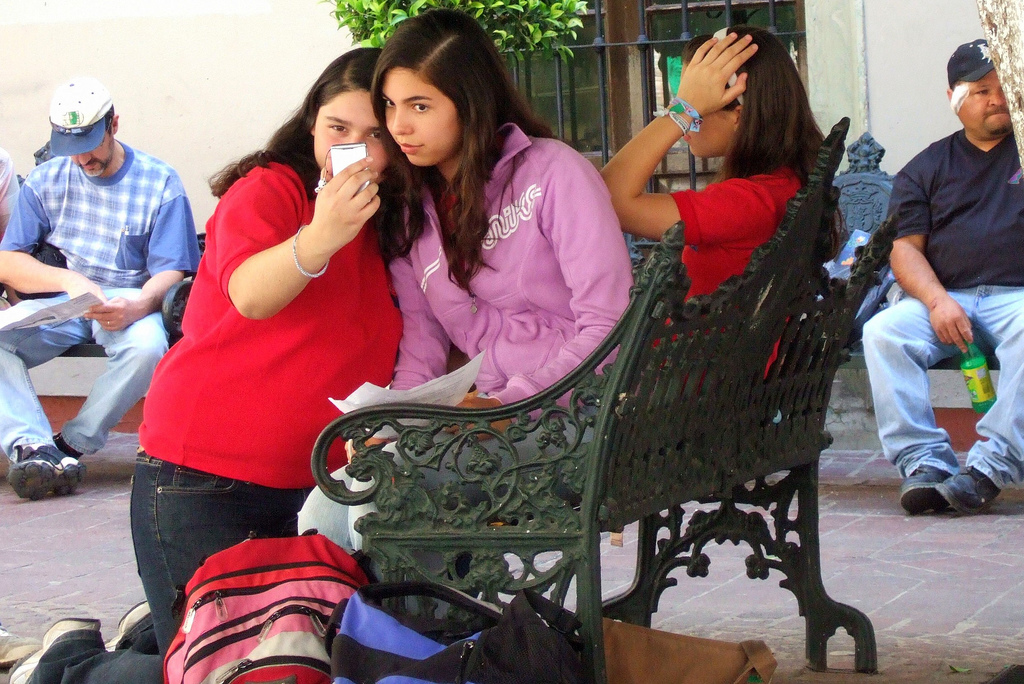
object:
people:
[578, 12, 866, 679]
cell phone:
[308, 130, 388, 196]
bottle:
[945, 312, 1001, 433]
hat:
[39, 61, 122, 163]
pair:
[0, 294, 177, 459]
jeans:
[0, 283, 173, 458]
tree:
[310, 0, 621, 161]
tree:
[332, 0, 617, 143]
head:
[357, 0, 554, 176]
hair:
[361, 4, 569, 308]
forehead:
[370, 72, 450, 99]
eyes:
[402, 89, 443, 119]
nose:
[381, 113, 422, 142]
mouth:
[381, 130, 438, 157]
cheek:
[417, 94, 466, 158]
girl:
[289, 0, 630, 573]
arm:
[181, 186, 341, 327]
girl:
[9, 47, 404, 679]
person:
[0, 80, 214, 510]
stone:
[874, 574, 1006, 639]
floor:
[0, 420, 1017, 678]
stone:
[859, 520, 1015, 581]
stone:
[676, 555, 797, 645]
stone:
[6, 522, 99, 575]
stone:
[829, 464, 901, 508]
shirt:
[139, 162, 400, 504]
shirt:
[361, 121, 644, 429]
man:
[850, 26, 1021, 529]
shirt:
[873, 130, 1024, 305]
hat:
[937, 37, 994, 97]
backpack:
[139, 510, 385, 682]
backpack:
[308, 579, 609, 682]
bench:
[269, 115, 941, 681]